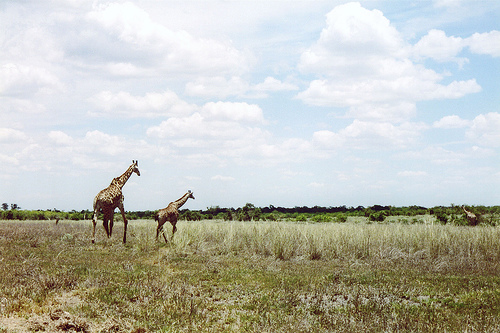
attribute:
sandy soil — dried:
[2, 304, 86, 331]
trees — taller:
[2, 195, 77, 236]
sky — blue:
[263, 37, 428, 142]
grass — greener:
[263, 212, 360, 220]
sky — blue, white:
[4, 4, 498, 207]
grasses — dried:
[1, 217, 498, 279]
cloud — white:
[302, 4, 416, 83]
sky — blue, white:
[53, 21, 461, 238]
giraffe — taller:
[88, 151, 141, 253]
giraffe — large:
[87, 162, 148, 256]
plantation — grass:
[0, 192, 482, 292]